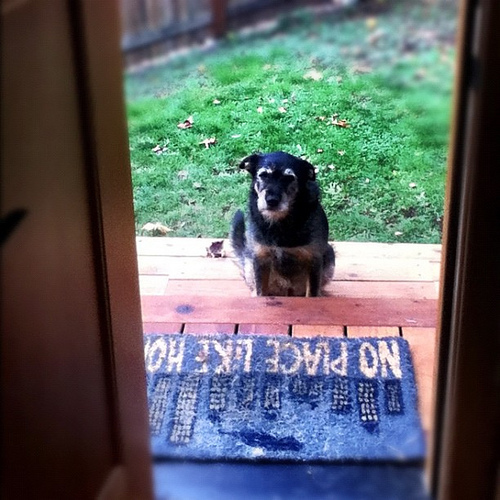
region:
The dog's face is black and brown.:
[253, 157, 298, 222]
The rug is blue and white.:
[155, 342, 409, 448]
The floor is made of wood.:
[362, 249, 433, 285]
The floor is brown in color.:
[350, 246, 429, 282]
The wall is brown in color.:
[46, 285, 112, 402]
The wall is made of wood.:
[23, 300, 92, 409]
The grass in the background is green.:
[267, 75, 341, 128]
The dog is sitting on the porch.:
[233, 149, 325, 300]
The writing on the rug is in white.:
[161, 337, 408, 374]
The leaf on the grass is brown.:
[332, 107, 352, 130]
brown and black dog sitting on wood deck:
[225, 150, 333, 297]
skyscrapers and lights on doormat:
[145, 375, 400, 445]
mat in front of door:
[137, 335, 422, 460]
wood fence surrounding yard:
[121, 0, 366, 67]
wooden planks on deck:
[135, 232, 430, 297]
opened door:
[0, 142, 151, 497]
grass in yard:
[121, 0, 456, 245]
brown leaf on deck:
[201, 240, 221, 255]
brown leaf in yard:
[178, 118, 195, 129]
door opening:
[118, 1, 464, 498]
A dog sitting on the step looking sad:
[206, 139, 356, 306]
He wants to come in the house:
[178, 124, 348, 296]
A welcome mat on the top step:
[156, 329, 421, 461]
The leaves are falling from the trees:
[199, 60, 369, 146]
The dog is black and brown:
[233, 152, 325, 224]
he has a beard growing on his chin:
[261, 209, 288, 226]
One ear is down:
[298, 160, 320, 188]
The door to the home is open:
[75, 125, 457, 465]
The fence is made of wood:
[141, 9, 226, 71]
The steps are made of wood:
[163, 294, 386, 332]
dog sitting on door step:
[222, 145, 346, 296]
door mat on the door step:
[140, 329, 430, 471]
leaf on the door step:
[205, 233, 226, 261]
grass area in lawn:
[332, 19, 441, 237]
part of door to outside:
[0, 2, 157, 495]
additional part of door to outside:
[425, 1, 497, 498]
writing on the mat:
[144, 329, 412, 385]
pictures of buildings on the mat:
[149, 379, 411, 449]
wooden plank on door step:
[143, 294, 435, 324]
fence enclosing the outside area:
[123, 3, 220, 45]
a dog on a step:
[222, 149, 339, 298]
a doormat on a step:
[135, 329, 430, 461]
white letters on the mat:
[142, 329, 402, 381]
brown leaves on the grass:
[132, 20, 464, 240]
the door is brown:
[4, 8, 169, 495]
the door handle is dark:
[0, 201, 31, 236]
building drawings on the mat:
[147, 374, 413, 449]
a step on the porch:
[129, 218, 446, 309]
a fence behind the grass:
[125, 2, 425, 76]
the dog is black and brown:
[231, 143, 342, 300]